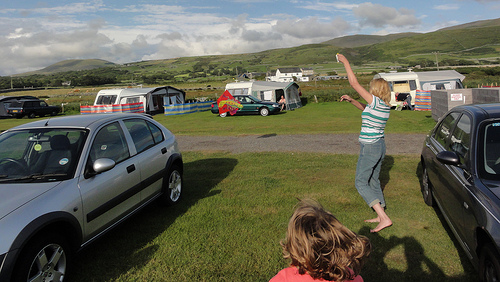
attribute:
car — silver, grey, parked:
[0, 115, 183, 281]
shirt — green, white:
[358, 96, 390, 144]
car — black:
[419, 104, 499, 282]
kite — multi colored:
[217, 91, 243, 116]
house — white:
[268, 67, 310, 83]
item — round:
[35, 142, 42, 152]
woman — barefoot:
[335, 51, 394, 233]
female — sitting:
[263, 195, 367, 281]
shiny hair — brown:
[282, 196, 373, 278]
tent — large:
[92, 86, 186, 116]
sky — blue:
[0, 0, 500, 74]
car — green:
[211, 94, 280, 117]